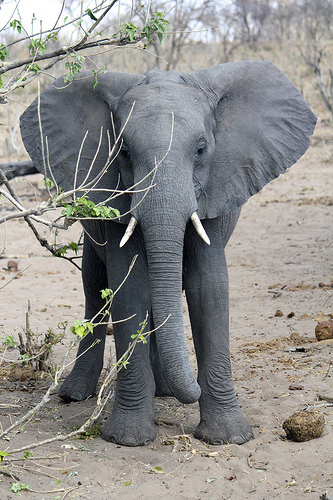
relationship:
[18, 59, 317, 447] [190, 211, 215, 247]
elephant has tusk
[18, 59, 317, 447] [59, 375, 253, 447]
elephant has feet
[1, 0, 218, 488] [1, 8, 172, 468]
tree has leaves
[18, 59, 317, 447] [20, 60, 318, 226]
elephant has ears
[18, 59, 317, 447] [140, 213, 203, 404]
elephant has trunk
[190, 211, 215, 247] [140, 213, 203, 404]
tusk next to trunk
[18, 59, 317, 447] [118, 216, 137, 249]
elephant has tusk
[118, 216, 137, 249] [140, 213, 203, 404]
tusk next to trunk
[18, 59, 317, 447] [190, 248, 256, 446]
elephant has leg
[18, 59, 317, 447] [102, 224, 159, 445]
elephant has leg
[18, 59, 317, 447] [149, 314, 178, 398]
elephant has leg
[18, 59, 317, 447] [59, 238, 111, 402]
elephant has leg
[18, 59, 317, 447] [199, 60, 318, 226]
elephant has ears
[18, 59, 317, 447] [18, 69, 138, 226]
elephant has ear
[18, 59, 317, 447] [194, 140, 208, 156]
elephant has eye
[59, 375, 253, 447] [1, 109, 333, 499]
feet on ground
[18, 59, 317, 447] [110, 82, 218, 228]
elephant has head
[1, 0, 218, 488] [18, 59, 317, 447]
tree next to elephant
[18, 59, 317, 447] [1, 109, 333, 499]
elephant on ground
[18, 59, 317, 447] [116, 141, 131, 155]
elephant has eye